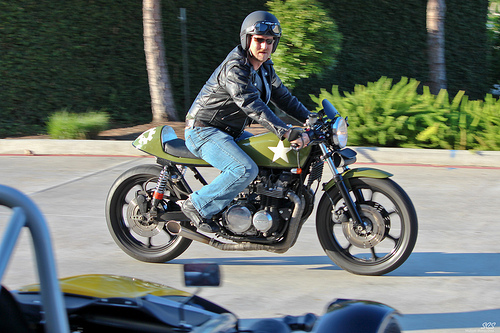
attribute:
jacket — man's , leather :
[181, 49, 299, 131]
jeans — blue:
[180, 126, 256, 216]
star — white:
[266, 139, 291, 162]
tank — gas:
[241, 125, 311, 167]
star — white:
[267, 138, 297, 164]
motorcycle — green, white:
[106, 98, 418, 275]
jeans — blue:
[189, 120, 251, 219]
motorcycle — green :
[162, 100, 386, 258]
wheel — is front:
[311, 168, 423, 281]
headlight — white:
[330, 114, 350, 147]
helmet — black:
[236, 9, 282, 57]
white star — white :
[269, 140, 299, 166]